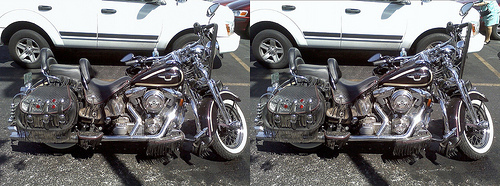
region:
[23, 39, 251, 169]
a brown bike is parked on the road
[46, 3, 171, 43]
a white car is passing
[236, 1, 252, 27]
the car is red in colour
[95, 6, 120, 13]
the door handles are black in colour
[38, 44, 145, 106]
the seat is blackin colour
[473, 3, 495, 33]
a woman is passing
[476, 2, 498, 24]
her dress is green in colour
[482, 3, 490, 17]
she has a black handbag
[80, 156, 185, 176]
the ground is grey in colour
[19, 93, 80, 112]
it has red lights on it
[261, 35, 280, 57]
the back wheel of a car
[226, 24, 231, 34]
the right indicator of a car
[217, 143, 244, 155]
the front tyre of a motorbike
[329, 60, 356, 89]
the seat of a motorbike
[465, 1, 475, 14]
the side mirror of a motor bike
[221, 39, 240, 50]
the bumper of a car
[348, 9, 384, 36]
the door of a car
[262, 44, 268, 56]
the rim of a the wheel of a car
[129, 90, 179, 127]
the engine of a motor bike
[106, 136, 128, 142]
the exhaust pipe of a motorbike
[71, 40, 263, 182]
this is a motorbike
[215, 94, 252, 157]
this is the wheel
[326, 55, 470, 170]
the motorbike is parked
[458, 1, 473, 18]
this is a mirror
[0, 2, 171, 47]
this is a car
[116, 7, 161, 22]
the car is white in color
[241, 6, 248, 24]
the car is red in color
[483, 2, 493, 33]
this is a lady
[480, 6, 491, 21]
this is a bag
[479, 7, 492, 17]
the bag is black in color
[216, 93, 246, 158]
the front wheel of a motorcycle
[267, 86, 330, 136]
a saddlebag on a motorcycle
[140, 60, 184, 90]
a motorcycle's gas tank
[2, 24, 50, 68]
the rear wheel of a vehicle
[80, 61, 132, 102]
the black leather motorcycle's driver seat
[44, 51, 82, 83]
black leather passenger seat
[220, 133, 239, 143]
spokes on a motorcycle wheel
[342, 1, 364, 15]
a black handle on a vehicle door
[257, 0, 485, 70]
a white vehicle with a black stripe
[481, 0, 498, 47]
a woman in a green dress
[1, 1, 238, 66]
side of white vehicle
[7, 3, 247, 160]
side of parked bike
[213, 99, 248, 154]
white wall of tire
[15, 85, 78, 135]
bag on side of bike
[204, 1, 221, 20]
mirror on bike handle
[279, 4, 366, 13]
black handles on white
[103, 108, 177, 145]
chrome pipes on bike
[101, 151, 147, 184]
shadow on paved surface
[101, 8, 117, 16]
handle on white door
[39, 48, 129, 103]
two seats on bike